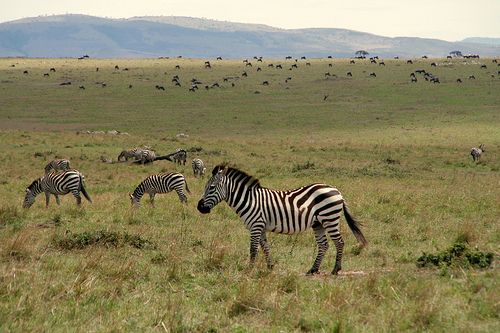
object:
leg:
[246, 220, 266, 263]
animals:
[19, 169, 93, 212]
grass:
[1, 59, 498, 331]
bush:
[403, 228, 497, 290]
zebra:
[131, 172, 190, 206]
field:
[0, 51, 499, 332]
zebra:
[469, 144, 486, 163]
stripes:
[258, 176, 313, 216]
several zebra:
[24, 143, 370, 272]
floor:
[198, 99, 304, 234]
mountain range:
[0, 11, 499, 61]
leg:
[259, 231, 271, 263]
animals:
[160, 86, 166, 91]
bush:
[53, 219, 158, 254]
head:
[199, 162, 245, 215]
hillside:
[0, 7, 499, 59]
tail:
[343, 197, 366, 246]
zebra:
[196, 163, 366, 276]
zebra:
[41, 158, 73, 173]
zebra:
[190, 158, 205, 177]